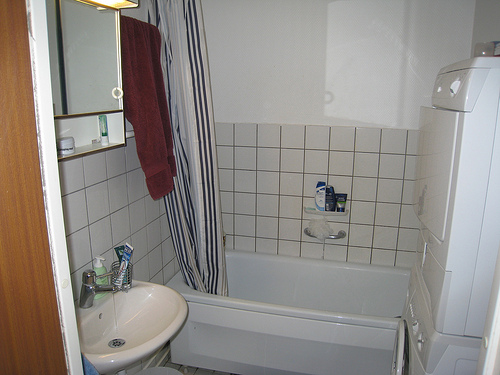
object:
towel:
[119, 14, 178, 201]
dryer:
[403, 55, 500, 375]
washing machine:
[391, 270, 500, 375]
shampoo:
[325, 186, 337, 212]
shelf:
[304, 207, 349, 216]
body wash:
[314, 181, 326, 211]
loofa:
[307, 217, 334, 243]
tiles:
[58, 121, 422, 285]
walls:
[46, 0, 476, 375]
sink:
[72, 279, 189, 375]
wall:
[46, 0, 184, 374]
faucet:
[79, 269, 116, 308]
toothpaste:
[113, 242, 134, 291]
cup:
[111, 261, 133, 291]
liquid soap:
[93, 256, 109, 300]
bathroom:
[25, 0, 498, 375]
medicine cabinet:
[46, 0, 127, 163]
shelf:
[54, 110, 128, 162]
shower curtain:
[160, 0, 228, 298]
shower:
[164, 0, 477, 375]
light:
[75, 0, 140, 11]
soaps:
[307, 181, 348, 213]